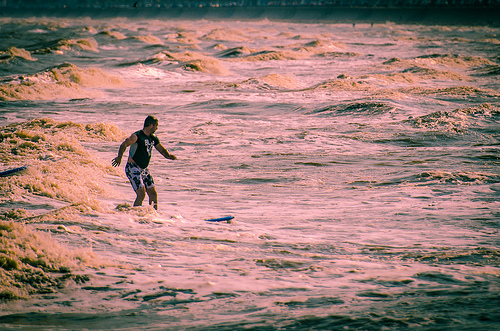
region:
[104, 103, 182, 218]
a man on the water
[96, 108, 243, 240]
man stands on surfboard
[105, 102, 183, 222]
surfer has extended arms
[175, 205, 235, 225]
surfboard in the ocean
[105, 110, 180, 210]
man with black tank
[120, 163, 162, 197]
short is white and black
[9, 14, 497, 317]
ocean is very dirty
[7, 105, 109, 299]
weeds are on the sea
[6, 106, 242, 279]
weeds behind a man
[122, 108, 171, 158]
man has black hair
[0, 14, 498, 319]
extremely rough water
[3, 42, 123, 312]
turbulent waves speeding toward shore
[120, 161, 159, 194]
black and white swim trunks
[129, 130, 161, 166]
black mens swim top with grey side panel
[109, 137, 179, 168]
arms out from sides for balance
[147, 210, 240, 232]
tip of a surf board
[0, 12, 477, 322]
water shines with coral hues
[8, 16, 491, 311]
light reflected off water means sun is low in the sky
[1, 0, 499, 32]
sky is looking darker on the horizon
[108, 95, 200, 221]
surger looking over his left shoulder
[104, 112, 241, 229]
Man is surfing on the water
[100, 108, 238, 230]
Man is surfing in the ocean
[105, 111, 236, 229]
Man is riding a wave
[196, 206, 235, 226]
Man is standing on a surfboard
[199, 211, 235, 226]
Man is standing on a blue surfboard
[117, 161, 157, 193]
Man is wearing shorts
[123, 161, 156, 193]
Man is wearing black and white shorts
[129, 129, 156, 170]
Man is wearing a shirt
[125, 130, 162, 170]
Man is wearing a black and white shirt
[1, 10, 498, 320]
Foam on top of the water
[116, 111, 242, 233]
surfer on a surfboard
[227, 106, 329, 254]
pink reflection from the sunset on water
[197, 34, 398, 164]
choppy waves colored by the sunset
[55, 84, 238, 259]
man surfing in choppy waves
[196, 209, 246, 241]
front of a surfboard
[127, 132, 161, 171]
black shirt with a white motif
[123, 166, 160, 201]
black and white board shorts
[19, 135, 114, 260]
white part of the waves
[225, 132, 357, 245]
calm part of the ocean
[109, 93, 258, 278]
man on a surf board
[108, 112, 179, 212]
man riding a surfboard in the ocean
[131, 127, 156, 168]
man in the oceans shirt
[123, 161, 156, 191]
man in the oceans short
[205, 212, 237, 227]
tip of mans surf board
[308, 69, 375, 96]
small wave in the ocean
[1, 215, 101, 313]
foamy wave in the ocean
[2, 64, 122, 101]
mild wave in the ocean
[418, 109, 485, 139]
ocean wave drifting away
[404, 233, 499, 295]
small ripple wave in the ocean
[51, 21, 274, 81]
region of waves in the ocean